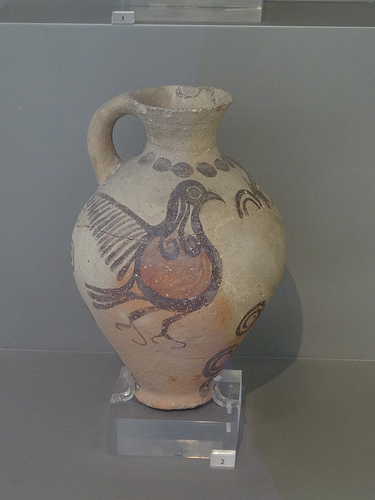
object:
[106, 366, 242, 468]
base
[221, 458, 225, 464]
2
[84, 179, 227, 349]
bird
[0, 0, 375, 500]
display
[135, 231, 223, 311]
belly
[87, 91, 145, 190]
handle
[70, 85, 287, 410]
pot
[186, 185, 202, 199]
eye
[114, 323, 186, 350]
feet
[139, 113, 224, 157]
neck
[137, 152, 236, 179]
black dots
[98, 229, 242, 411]
orange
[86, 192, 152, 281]
wings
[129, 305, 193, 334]
legs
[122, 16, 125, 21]
1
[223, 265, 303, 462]
shadow